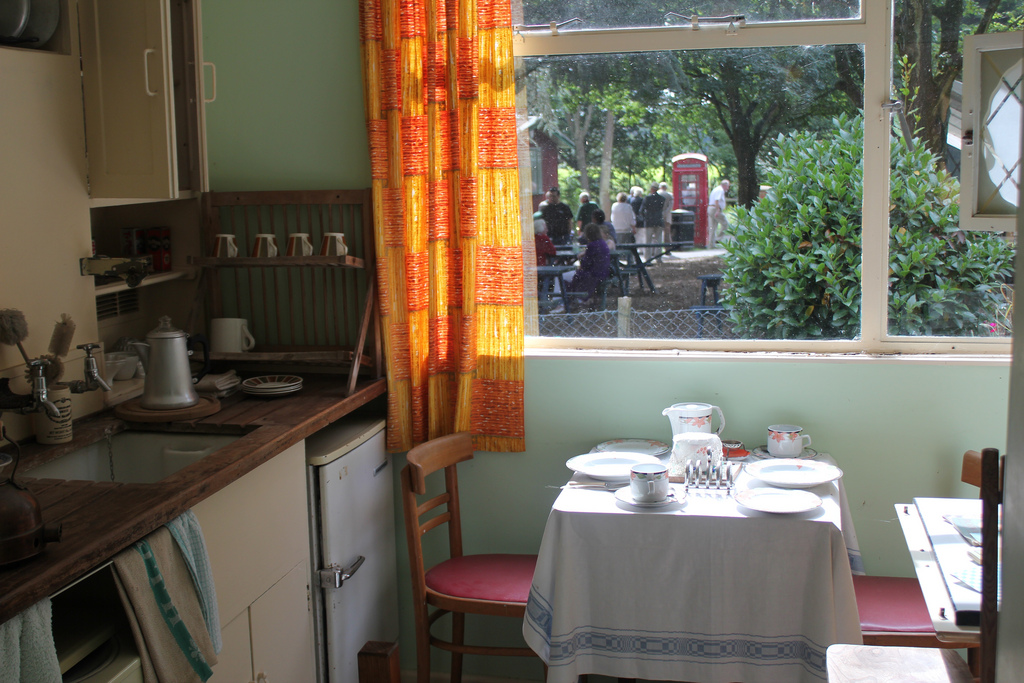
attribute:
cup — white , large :
[210, 312, 258, 364]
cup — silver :
[128, 332, 193, 406]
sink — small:
[36, 423, 287, 508]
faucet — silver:
[77, 343, 112, 402]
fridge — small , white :
[319, 407, 425, 663]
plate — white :
[567, 446, 663, 485]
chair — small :
[401, 435, 540, 680]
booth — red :
[666, 148, 712, 244]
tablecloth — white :
[532, 444, 861, 680]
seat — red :
[429, 556, 540, 609]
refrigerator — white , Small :
[299, 421, 423, 677]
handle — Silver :
[318, 556, 370, 587]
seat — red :
[426, 548, 548, 601]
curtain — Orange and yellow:
[364, 1, 537, 473]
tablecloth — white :
[543, 464, 853, 678]